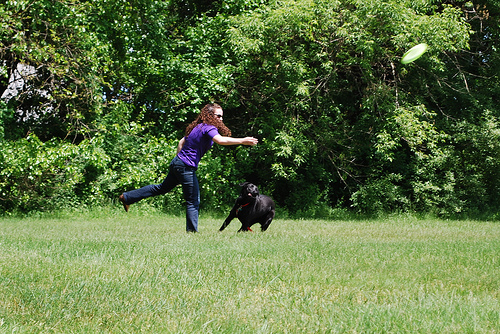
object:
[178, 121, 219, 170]
shirt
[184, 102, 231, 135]
hair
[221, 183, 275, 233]
dog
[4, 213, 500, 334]
field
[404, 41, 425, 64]
frisbee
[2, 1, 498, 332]
air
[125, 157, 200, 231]
jeans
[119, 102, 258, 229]
lady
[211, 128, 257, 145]
arm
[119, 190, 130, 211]
shoe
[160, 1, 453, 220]
tree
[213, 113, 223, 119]
sunglasses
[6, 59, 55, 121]
sky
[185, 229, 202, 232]
foot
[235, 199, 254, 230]
leash